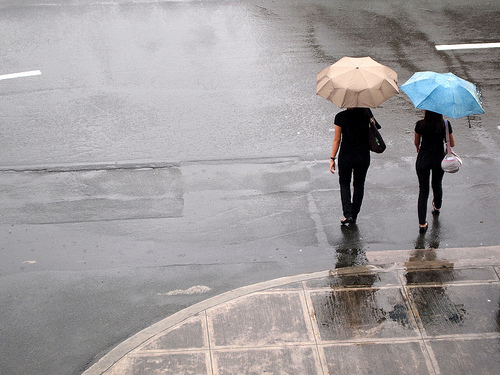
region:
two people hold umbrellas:
[284, 50, 464, 272]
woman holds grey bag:
[414, 103, 475, 200]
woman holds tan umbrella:
[317, 67, 389, 122]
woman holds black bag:
[358, 100, 413, 172]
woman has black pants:
[410, 153, 454, 213]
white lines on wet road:
[7, 51, 57, 95]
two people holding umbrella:
[307, 45, 493, 247]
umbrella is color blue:
[397, 64, 486, 120]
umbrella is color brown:
[308, 51, 405, 113]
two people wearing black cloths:
[322, 100, 458, 237]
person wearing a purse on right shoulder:
[410, 110, 460, 236]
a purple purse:
[439, 118, 465, 176]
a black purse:
[363, 109, 392, 156]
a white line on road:
[427, 28, 499, 53]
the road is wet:
[7, 3, 307, 270]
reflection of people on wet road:
[318, 246, 475, 361]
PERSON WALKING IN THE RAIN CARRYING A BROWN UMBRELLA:
[325, 104, 387, 227]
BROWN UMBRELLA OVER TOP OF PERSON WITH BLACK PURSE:
[313, 52, 400, 115]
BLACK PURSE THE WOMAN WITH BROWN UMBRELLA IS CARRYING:
[366, 119, 388, 154]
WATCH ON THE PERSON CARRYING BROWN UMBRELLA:
[328, 153, 337, 163]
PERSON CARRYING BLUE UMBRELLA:
[414, 108, 456, 237]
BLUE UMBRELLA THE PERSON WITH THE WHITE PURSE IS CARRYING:
[401, 68, 486, 128]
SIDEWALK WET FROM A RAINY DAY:
[74, 261, 499, 370]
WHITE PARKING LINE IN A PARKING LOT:
[1, 69, 45, 83]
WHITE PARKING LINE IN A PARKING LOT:
[433, 37, 498, 57]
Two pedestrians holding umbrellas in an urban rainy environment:
[313, 48, 490, 256]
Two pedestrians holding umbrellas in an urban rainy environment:
[305, 51, 490, 252]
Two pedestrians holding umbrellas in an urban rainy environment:
[309, 47, 488, 259]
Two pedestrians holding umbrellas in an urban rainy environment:
[309, 50, 489, 249]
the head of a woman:
[421, 103, 448, 129]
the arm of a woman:
[403, 126, 431, 156]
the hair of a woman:
[411, 108, 453, 139]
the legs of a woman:
[396, 143, 474, 240]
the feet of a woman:
[409, 185, 459, 236]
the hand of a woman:
[305, 147, 363, 192]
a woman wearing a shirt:
[314, 83, 413, 165]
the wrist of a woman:
[320, 138, 350, 177]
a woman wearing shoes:
[319, 175, 402, 231]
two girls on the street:
[273, 98, 471, 229]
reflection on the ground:
[290, 238, 385, 310]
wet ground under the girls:
[241, 211, 331, 268]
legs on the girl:
[390, 165, 464, 228]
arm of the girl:
[301, 113, 362, 186]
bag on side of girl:
[418, 116, 476, 200]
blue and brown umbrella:
[298, 38, 485, 114]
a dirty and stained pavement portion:
[198, 285, 317, 351]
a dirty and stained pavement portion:
[297, 275, 431, 350]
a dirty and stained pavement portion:
[118, 293, 213, 355]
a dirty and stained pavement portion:
[82, 343, 212, 373]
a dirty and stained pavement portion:
[203, 344, 328, 374]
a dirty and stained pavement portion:
[309, 337, 429, 373]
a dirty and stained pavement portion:
[298, 266, 413, 302]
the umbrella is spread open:
[316, 50, 398, 109]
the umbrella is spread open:
[406, 68, 481, 121]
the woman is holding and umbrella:
[307, 40, 399, 237]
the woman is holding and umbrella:
[404, 63, 477, 234]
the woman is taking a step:
[316, 55, 393, 234]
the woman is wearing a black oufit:
[337, 107, 379, 227]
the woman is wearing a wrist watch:
[329, 154, 335, 161]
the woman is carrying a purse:
[363, 108, 384, 153]